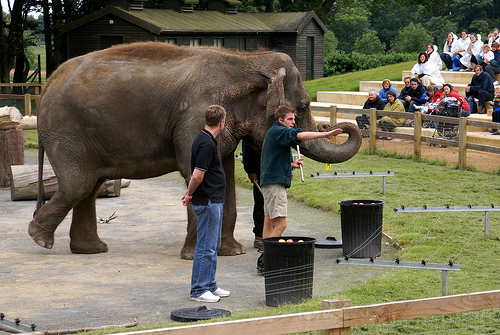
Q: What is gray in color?
A: Elephant.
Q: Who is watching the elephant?
A: Crowd of people.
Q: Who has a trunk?
A: An elephant.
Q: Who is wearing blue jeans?
A: Man on left.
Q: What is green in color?
A: Grass.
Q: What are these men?
A: Handlers.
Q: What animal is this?
A: Elephant.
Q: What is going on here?
A: Demonstration.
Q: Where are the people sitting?
A: Bleachers.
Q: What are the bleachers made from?
A: Wood.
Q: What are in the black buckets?
A: Apples.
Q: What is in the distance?
A: Brown building.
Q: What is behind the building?
A: Trees.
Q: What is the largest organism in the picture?
A: An elephant.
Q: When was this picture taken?
A: Day time.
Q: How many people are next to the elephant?
A: Two.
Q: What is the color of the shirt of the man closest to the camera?
A: Black.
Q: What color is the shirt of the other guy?
A: Green.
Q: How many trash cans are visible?
A: Two.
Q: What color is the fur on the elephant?
A: Orange.